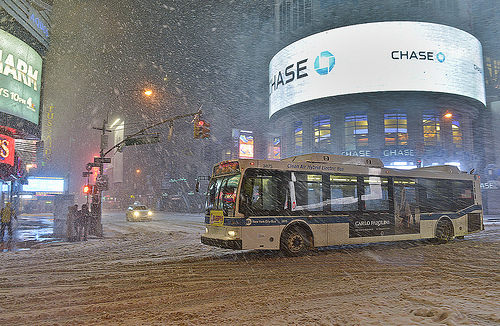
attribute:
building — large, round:
[412, 123, 427, 164]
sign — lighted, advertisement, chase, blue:
[339, 23, 390, 89]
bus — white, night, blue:
[215, 158, 424, 245]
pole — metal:
[71, 179, 115, 219]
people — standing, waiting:
[1, 192, 115, 243]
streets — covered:
[102, 281, 178, 309]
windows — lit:
[311, 114, 330, 149]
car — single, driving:
[132, 206, 147, 223]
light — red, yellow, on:
[127, 77, 154, 102]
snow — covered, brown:
[156, 8, 175, 30]